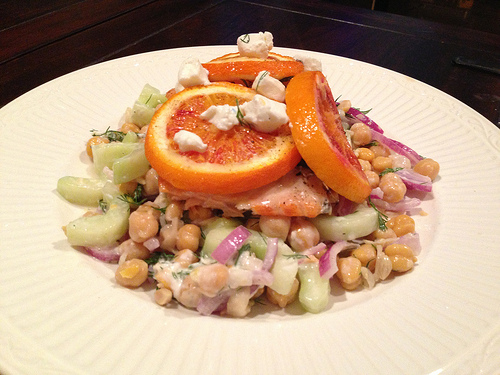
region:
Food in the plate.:
[103, 72, 398, 302]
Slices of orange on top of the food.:
[167, 78, 287, 179]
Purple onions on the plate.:
[213, 226, 353, 271]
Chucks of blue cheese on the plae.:
[191, 74, 289, 139]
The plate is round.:
[2, 54, 100, 373]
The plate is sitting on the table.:
[33, 19, 479, 177]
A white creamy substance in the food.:
[124, 237, 264, 301]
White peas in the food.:
[333, 224, 432, 297]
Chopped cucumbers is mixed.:
[58, 127, 150, 252]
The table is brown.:
[360, 9, 449, 71]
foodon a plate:
[85, 56, 492, 351]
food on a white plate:
[71, 64, 444, 372]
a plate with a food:
[7, 43, 440, 365]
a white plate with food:
[34, 55, 487, 348]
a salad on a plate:
[64, 76, 423, 301]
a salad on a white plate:
[86, 63, 444, 350]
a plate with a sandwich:
[37, 46, 497, 367]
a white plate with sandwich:
[44, 40, 474, 368]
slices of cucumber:
[122, 46, 466, 350]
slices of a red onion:
[91, 63, 421, 351]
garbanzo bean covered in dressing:
[128, 206, 158, 245]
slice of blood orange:
[146, 89, 300, 184]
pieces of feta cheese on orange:
[170, 93, 281, 148]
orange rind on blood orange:
[143, 130, 308, 195]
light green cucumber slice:
[60, 177, 128, 247]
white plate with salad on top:
[19, 54, 488, 368]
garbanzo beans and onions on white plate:
[337, 123, 445, 295]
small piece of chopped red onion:
[212, 220, 248, 259]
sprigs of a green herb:
[120, 183, 162, 210]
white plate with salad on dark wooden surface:
[5, 12, 495, 372]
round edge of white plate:
[56, 58, 107, 89]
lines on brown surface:
[84, 19, 192, 44]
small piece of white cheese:
[231, 19, 276, 53]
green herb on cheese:
[225, 95, 255, 129]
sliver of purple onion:
[204, 225, 259, 260]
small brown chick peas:
[110, 256, 150, 288]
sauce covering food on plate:
[260, 183, 312, 209]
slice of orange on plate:
[288, 67, 372, 184]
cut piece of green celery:
[46, 175, 159, 254]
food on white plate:
[79, 46, 416, 277]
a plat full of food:
[100, 39, 383, 327]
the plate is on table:
[74, 14, 456, 241]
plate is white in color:
[183, 301, 308, 374]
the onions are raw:
[208, 227, 380, 326]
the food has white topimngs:
[178, 26, 336, 172]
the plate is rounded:
[65, 70, 437, 355]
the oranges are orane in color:
[188, 60, 353, 205]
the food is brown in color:
[119, 187, 239, 304]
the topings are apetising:
[181, 94, 294, 162]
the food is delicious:
[120, 65, 355, 311]